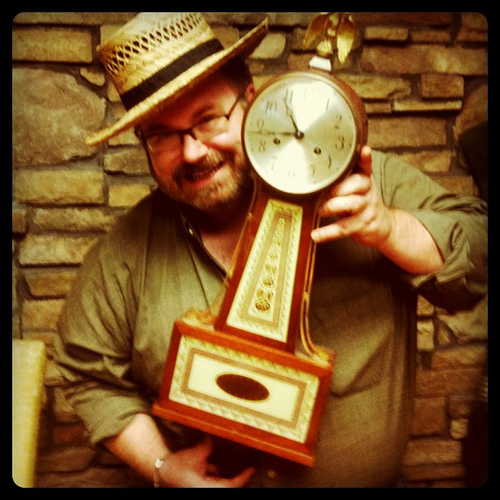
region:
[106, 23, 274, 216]
head of a person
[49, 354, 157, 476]
arm of a person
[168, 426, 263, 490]
hand of a person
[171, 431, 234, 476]
finger of a person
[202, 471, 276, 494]
finger of a person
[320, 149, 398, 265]
hand of a person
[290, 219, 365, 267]
pinky of a person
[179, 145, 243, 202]
mouth of a person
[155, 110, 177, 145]
eye of a person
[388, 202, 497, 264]
arm of a person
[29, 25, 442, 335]
Wall is brown color.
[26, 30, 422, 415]
Wall is made of stones.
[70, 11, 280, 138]
Man is wearing brown hat.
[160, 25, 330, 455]
Clock is brown and golden color.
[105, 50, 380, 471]
Man is holding the clock in hand.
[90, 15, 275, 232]
Man is wearing eye glass in eyes.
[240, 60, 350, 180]
10.44 is the time shown in clock.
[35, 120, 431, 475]
Man is wearing brown shirt.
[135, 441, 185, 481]
Man is wearing bracelet in hand.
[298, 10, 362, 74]
Bird symbol in top of the clock.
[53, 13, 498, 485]
This is a person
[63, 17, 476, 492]
This is a person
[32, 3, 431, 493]
This is a person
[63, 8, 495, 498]
This is a person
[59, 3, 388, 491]
This is a person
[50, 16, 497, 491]
This is a person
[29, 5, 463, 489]
This is a person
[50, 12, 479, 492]
This is a person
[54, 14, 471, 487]
This is a person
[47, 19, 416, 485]
this is a man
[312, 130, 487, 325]
this is a hand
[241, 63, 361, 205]
this is a clock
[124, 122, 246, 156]
the man is in glasses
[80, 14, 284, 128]
this is a hat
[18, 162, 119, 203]
this is a block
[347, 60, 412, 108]
this is a block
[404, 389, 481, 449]
this is a block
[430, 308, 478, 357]
this is a block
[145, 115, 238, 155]
glasses on the man's face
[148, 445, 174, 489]
bracelet on man's wrist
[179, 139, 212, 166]
the nose on the man's face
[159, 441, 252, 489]
the man's right hand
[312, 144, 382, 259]
the man's left hand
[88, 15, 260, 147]
hat on the man's head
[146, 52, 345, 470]
wooden clock held by the man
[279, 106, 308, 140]
black hour hand on clock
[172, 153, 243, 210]
the beard on the man's face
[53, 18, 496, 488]
Man holding clock in front of stone wall.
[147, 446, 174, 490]
Pale wrist covered by silver bracelet.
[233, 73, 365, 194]
Clock face reading 10:43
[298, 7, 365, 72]
Edge of bronze bird adorning trophy.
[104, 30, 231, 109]
Black band around hat.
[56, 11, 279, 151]
Straw hat with black band.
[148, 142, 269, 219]
Brown beard and mustache.